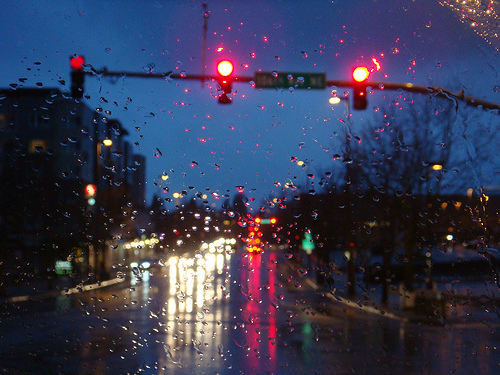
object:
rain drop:
[160, 166, 207, 211]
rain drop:
[286, 172, 320, 218]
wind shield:
[0, 0, 499, 374]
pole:
[98, 71, 500, 113]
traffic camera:
[198, 6, 208, 89]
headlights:
[130, 261, 138, 269]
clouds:
[219, 120, 256, 155]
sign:
[301, 232, 316, 254]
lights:
[163, 255, 178, 269]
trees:
[269, 70, 500, 320]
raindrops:
[2, 0, 259, 46]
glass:
[2, 0, 500, 375]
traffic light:
[66, 52, 86, 98]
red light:
[216, 60, 235, 77]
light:
[141, 262, 150, 269]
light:
[212, 58, 233, 105]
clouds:
[86, 23, 148, 59]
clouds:
[147, 24, 237, 66]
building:
[0, 86, 153, 250]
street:
[40, 171, 449, 373]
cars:
[246, 244, 263, 253]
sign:
[252, 67, 329, 92]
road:
[190, 243, 282, 365]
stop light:
[250, 214, 261, 237]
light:
[350, 66, 369, 111]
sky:
[0, 2, 498, 214]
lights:
[253, 216, 276, 225]